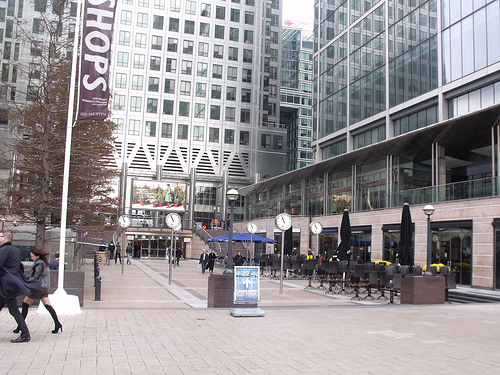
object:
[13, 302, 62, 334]
boots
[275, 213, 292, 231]
clock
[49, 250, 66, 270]
people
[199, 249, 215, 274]
people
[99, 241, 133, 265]
people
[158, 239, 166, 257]
door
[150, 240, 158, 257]
door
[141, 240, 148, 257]
door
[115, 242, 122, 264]
person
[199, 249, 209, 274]
person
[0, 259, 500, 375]
tile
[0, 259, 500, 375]
floor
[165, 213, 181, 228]
clock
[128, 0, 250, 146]
windows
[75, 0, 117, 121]
banner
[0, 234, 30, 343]
man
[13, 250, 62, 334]
lady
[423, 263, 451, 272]
flower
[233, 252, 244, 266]
person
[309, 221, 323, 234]
clocks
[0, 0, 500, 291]
building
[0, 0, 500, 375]
photo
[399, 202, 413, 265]
umbrella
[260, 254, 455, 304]
seating area